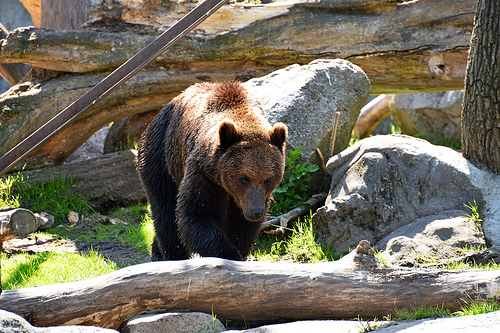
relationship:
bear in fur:
[132, 79, 290, 269] [196, 65, 259, 120]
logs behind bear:
[4, 4, 471, 154] [134, 78, 289, 165]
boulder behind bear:
[245, 54, 372, 174] [132, 79, 290, 269]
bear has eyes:
[132, 79, 290, 269] [239, 175, 252, 188]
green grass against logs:
[1, 176, 98, 226] [0, 146, 147, 233]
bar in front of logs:
[0, 0, 227, 179] [0, 18, 497, 206]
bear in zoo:
[132, 79, 290, 269] [0, 0, 495, 332]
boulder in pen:
[308, 126, 498, 277] [2, 1, 498, 328]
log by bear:
[0, 256, 495, 327] [132, 79, 290, 269]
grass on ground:
[11, 130, 498, 323] [0, 132, 499, 331]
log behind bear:
[12, 153, 151, 223] [132, 79, 290, 269]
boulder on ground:
[308, 132, 500, 270] [40, 188, 142, 288]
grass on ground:
[0, 131, 498, 332] [42, 239, 94, 271]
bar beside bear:
[0, 0, 227, 179] [132, 79, 290, 269]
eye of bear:
[241, 176, 252, 188] [132, 79, 290, 269]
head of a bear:
[217, 122, 287, 222] [132, 79, 290, 269]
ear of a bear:
[213, 117, 242, 154] [132, 79, 290, 269]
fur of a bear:
[203, 74, 247, 114] [132, 79, 290, 269]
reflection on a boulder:
[252, 80, 312, 105] [237, 54, 373, 186]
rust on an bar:
[56, 60, 145, 110] [0, 0, 227, 179]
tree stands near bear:
[448, 40, 495, 161] [132, 74, 297, 275]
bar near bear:
[0, 0, 227, 179] [138, 78, 301, 283]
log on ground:
[0, 238, 499, 330] [0, 132, 499, 331]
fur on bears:
[177, 85, 229, 115] [135, 80, 292, 262]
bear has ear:
[132, 79, 290, 269] [216, 117, 245, 147]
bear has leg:
[132, 79, 290, 269] [176, 148, 226, 257]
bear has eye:
[132, 79, 290, 269] [259, 175, 282, 196]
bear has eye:
[129, 76, 309, 277] [262, 176, 274, 188]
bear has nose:
[132, 79, 290, 269] [251, 208, 265, 218]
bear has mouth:
[132, 79, 290, 269] [233, 193, 274, 223]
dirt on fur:
[190, 191, 206, 210] [136, 79, 286, 260]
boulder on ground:
[308, 132, 500, 270] [0, 132, 499, 331]